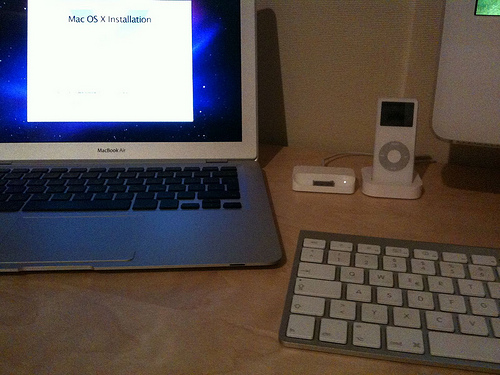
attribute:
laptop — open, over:
[32, 33, 263, 260]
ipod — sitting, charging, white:
[367, 81, 417, 197]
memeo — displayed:
[49, 27, 217, 135]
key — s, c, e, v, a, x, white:
[321, 266, 424, 328]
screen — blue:
[23, 47, 202, 122]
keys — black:
[37, 174, 231, 216]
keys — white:
[363, 241, 449, 304]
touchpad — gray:
[58, 210, 147, 251]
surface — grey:
[102, 185, 207, 249]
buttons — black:
[146, 166, 217, 198]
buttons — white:
[324, 248, 433, 300]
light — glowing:
[337, 174, 367, 201]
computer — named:
[27, 17, 298, 271]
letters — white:
[324, 257, 432, 330]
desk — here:
[140, 285, 238, 347]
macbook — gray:
[49, 213, 251, 277]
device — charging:
[296, 138, 421, 217]